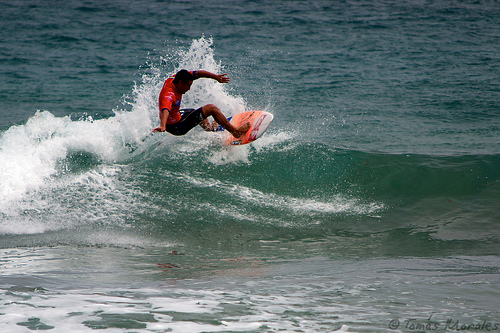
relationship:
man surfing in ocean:
[151, 66, 254, 137] [1, 1, 496, 331]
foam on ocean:
[2, 37, 299, 221] [1, 1, 496, 331]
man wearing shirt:
[151, 66, 254, 137] [156, 67, 198, 125]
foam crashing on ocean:
[2, 37, 299, 221] [1, 1, 496, 331]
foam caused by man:
[2, 37, 299, 221] [151, 66, 254, 137]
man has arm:
[151, 66, 254, 137] [188, 68, 229, 85]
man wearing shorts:
[151, 66, 254, 137] [167, 105, 208, 136]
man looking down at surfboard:
[151, 66, 254, 137] [192, 111, 276, 147]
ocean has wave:
[1, 1, 496, 331] [2, 124, 499, 230]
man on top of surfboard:
[151, 66, 254, 137] [192, 111, 276, 147]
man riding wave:
[151, 66, 254, 137] [2, 124, 499, 230]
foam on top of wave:
[2, 37, 299, 221] [2, 124, 499, 230]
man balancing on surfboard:
[151, 66, 254, 137] [192, 111, 276, 147]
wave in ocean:
[2, 124, 499, 230] [1, 1, 496, 331]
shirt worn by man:
[156, 67, 198, 125] [151, 66, 254, 137]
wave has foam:
[2, 124, 499, 230] [2, 37, 299, 221]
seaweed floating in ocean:
[155, 259, 182, 271] [1, 1, 496, 331]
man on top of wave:
[151, 66, 254, 137] [2, 124, 499, 230]